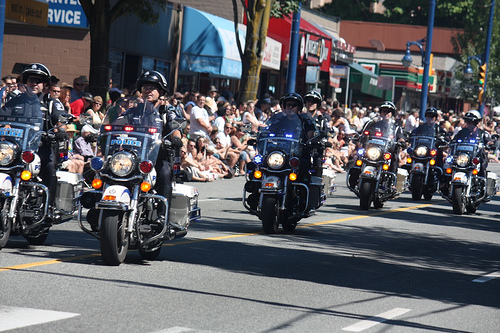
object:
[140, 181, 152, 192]
light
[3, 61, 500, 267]
seven cops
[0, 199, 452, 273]
line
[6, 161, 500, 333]
road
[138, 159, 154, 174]
light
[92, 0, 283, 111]
building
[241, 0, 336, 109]
building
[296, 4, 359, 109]
building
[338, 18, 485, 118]
building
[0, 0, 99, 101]
building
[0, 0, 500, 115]
row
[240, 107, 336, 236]
motorcycle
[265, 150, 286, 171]
light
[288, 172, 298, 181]
light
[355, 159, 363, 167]
light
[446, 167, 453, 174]
light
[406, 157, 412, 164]
light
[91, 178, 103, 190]
light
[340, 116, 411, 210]
motorcycle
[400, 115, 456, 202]
motorcycle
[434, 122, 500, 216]
motorcycle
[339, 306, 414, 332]
lines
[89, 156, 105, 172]
light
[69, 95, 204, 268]
motorcycle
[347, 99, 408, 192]
cop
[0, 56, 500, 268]
group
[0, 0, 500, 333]
public event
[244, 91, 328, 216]
cops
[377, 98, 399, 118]
helmets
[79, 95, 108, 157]
spectators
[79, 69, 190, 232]
cops